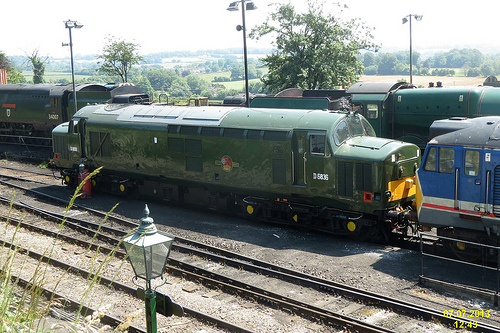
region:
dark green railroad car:
[49, 97, 414, 251]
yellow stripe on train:
[384, 175, 426, 198]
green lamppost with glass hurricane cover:
[123, 204, 175, 330]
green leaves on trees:
[250, 1, 382, 89]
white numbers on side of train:
[311, 170, 331, 184]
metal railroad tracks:
[16, 176, 485, 331]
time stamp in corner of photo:
[440, 300, 498, 331]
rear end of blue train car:
[410, 121, 499, 265]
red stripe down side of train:
[420, 195, 498, 223]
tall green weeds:
[4, 163, 134, 331]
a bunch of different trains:
[1, 63, 499, 265]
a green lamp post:
[136, 287, 169, 332]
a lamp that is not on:
[110, 203, 189, 330]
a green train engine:
[44, 78, 418, 243]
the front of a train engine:
[318, 98, 425, 253]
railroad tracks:
[0, 143, 496, 331]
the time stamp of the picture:
[441, 303, 493, 331]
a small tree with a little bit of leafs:
[91, 27, 141, 82]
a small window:
[306, 132, 328, 157]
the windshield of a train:
[336, 110, 377, 145]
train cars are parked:
[0, 73, 499, 259]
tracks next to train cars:
[0, 165, 499, 332]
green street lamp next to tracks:
[119, 203, 176, 332]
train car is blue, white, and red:
[416, 115, 498, 262]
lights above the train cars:
[59, 0, 424, 114]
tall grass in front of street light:
[0, 163, 154, 331]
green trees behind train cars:
[0, 0, 498, 105]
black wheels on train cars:
[113, 178, 480, 260]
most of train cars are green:
[0, 71, 498, 238]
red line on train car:
[422, 202, 499, 218]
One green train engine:
[11, 97, 408, 234]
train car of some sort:
[396, 145, 498, 260]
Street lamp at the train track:
[122, 191, 174, 328]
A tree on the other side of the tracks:
[238, 6, 378, 86]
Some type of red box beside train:
[65, 151, 93, 205]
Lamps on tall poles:
[218, 2, 268, 102]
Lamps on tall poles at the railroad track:
[56, 12, 88, 217]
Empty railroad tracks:
[11, 192, 193, 317]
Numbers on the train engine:
[296, 162, 338, 194]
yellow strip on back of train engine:
[382, 148, 424, 220]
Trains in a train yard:
[5, 62, 497, 249]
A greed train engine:
[31, 97, 426, 232]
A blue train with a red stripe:
[407, 100, 497, 236]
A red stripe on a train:
[416, 193, 498, 231]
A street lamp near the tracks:
[108, 201, 179, 324]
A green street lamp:
[115, 203, 192, 325]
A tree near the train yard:
[245, 3, 384, 87]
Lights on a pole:
[221, 1, 272, 103]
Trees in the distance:
[10, 43, 244, 104]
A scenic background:
[77, 42, 269, 102]